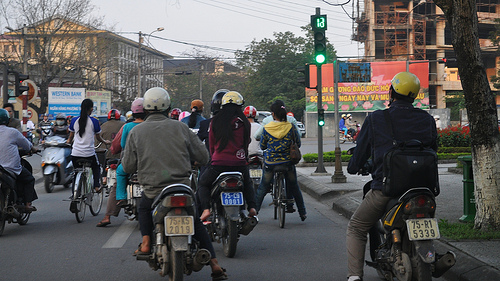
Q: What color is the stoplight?
A: Green.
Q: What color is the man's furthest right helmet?
A: Yellow.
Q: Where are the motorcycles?
A: On the road.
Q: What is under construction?
A: Tall building.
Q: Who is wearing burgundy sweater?
A: Girl with her back to camera.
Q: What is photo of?
A: People riding bikes and motorcycles.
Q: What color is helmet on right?
A: Yellow.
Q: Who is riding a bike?
A: The woman.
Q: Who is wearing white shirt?
A: Woman riding a bike.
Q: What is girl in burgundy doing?
A: Riding bike with another person.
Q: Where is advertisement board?
A: Corner of street.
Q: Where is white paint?
A: Trunk of tree.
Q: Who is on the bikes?
A: The people.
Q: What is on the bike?
A: License plates.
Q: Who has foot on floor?
A: Biker.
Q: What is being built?
A: Building.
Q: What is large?
A: Building.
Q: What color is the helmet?
A: Yellow.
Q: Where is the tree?
A: Side of road.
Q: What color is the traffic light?
A: Green.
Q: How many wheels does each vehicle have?
A: 2.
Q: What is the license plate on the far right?
A: 75-R1 5339.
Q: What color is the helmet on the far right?
A: Yellow.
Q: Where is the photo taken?
A: A city.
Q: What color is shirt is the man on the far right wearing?
A: Navy.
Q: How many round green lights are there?
A: Two.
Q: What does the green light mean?
A: Go.